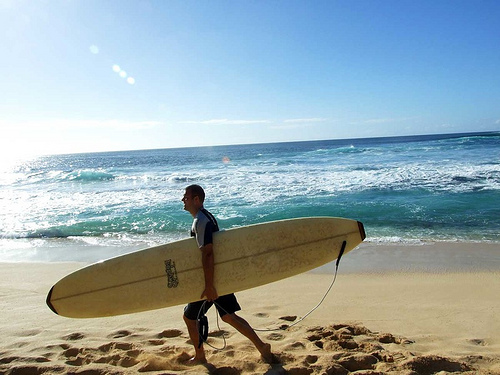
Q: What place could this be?
A: It is a beach.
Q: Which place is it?
A: It is a beach.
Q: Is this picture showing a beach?
A: Yes, it is showing a beach.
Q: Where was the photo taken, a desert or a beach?
A: It was taken at a beach.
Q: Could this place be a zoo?
A: No, it is a beach.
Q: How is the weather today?
A: It is sunny.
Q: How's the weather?
A: It is sunny.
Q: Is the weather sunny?
A: Yes, it is sunny.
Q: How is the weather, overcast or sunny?
A: It is sunny.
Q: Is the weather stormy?
A: No, it is sunny.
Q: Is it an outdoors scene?
A: Yes, it is outdoors.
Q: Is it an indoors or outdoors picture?
A: It is outdoors.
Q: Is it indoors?
A: No, it is outdoors.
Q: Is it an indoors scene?
A: No, it is outdoors.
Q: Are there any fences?
A: No, there are no fences.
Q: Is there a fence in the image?
A: No, there are no fences.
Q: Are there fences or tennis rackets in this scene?
A: No, there are no fences or tennis rackets.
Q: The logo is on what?
A: The logo is on the surf board.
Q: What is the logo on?
A: The logo is on the surf board.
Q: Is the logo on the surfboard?
A: Yes, the logo is on the surfboard.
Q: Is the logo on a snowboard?
A: No, the logo is on the surfboard.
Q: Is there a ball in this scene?
A: No, there are no balls.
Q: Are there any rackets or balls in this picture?
A: No, there are no balls or rackets.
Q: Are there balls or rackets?
A: No, there are no balls or rackets.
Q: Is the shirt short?
A: Yes, the shirt is short.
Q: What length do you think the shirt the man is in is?
A: The shirt is short.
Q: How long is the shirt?
A: The shirt is short.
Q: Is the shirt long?
A: No, the shirt is short.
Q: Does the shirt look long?
A: No, the shirt is short.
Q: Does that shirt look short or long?
A: The shirt is short.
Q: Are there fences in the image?
A: No, there are no fences.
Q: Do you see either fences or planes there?
A: No, there are no fences or planes.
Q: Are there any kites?
A: No, there are no kites.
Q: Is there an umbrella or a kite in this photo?
A: No, there are no kites or umbrellas.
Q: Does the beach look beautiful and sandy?
A: Yes, the beach is beautiful and sandy.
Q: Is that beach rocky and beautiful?
A: No, the beach is beautiful but sandy.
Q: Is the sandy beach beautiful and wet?
A: Yes, the beach is beautiful and wet.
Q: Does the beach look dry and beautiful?
A: No, the beach is beautiful but wet.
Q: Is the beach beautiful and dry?
A: No, the beach is beautiful but wet.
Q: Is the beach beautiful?
A: Yes, the beach is beautiful.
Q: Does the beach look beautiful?
A: Yes, the beach is beautiful.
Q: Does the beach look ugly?
A: No, the beach is beautiful.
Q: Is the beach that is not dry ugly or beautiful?
A: The beach is beautiful.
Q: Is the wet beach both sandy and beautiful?
A: Yes, the beach is sandy and beautiful.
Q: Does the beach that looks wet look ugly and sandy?
A: No, the beach is sandy but beautiful.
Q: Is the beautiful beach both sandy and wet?
A: Yes, the beach is sandy and wet.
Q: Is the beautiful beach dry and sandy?
A: No, the beach is sandy but wet.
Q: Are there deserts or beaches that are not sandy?
A: No, there is a beach but it is sandy.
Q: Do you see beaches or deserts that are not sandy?
A: No, there is a beach but it is sandy.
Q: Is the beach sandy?
A: Yes, the beach is sandy.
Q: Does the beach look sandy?
A: Yes, the beach is sandy.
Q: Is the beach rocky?
A: No, the beach is sandy.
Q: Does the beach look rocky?
A: No, the beach is sandy.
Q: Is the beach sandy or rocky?
A: The beach is sandy.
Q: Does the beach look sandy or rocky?
A: The beach is sandy.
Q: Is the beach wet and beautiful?
A: Yes, the beach is wet and beautiful.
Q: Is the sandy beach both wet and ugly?
A: No, the beach is wet but beautiful.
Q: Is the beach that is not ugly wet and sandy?
A: Yes, the beach is wet and sandy.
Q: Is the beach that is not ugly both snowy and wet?
A: No, the beach is wet but sandy.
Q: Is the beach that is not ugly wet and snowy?
A: No, the beach is wet but sandy.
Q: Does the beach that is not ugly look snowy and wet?
A: No, the beach is wet but sandy.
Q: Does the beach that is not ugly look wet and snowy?
A: No, the beach is wet but sandy.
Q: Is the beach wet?
A: Yes, the beach is wet.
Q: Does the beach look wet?
A: Yes, the beach is wet.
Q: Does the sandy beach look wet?
A: Yes, the beach is wet.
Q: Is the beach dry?
A: No, the beach is wet.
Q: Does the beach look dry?
A: No, the beach is wet.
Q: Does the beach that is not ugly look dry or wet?
A: The beach is wet.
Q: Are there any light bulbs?
A: No, there are no light bulbs.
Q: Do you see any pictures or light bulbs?
A: No, there are no light bulbs or pictures.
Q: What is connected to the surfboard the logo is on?
A: The rope is connected to the surfboard.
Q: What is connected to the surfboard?
A: The rope is connected to the surfboard.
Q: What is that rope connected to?
A: The rope is connected to the surfboard.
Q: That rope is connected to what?
A: The rope is connected to the surfboard.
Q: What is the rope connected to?
A: The rope is connected to the surfboard.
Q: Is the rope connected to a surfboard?
A: Yes, the rope is connected to a surfboard.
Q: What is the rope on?
A: The rope is on the surfboard.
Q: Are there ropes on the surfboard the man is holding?
A: Yes, there is a rope on the surfboard.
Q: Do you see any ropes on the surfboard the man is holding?
A: Yes, there is a rope on the surfboard.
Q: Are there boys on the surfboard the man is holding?
A: No, there is a rope on the surfboard.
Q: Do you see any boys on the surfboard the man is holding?
A: No, there is a rope on the surfboard.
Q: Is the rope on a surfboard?
A: Yes, the rope is on a surfboard.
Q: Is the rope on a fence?
A: No, the rope is on a surfboard.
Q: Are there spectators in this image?
A: No, there are no spectators.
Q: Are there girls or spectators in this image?
A: No, there are no spectators or girls.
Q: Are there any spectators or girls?
A: No, there are no spectators or girls.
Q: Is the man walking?
A: Yes, the man is walking.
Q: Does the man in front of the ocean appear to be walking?
A: Yes, the man is walking.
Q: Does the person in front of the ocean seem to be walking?
A: Yes, the man is walking.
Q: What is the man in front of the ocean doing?
A: The man is walking.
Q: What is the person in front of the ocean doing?
A: The man is walking.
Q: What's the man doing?
A: The man is walking.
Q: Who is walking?
A: The man is walking.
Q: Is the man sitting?
A: No, the man is walking.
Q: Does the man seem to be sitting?
A: No, the man is walking.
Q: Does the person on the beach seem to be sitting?
A: No, the man is walking.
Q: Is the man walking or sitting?
A: The man is walking.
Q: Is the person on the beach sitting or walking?
A: The man is walking.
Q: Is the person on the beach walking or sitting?
A: The man is walking.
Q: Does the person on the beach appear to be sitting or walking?
A: The man is walking.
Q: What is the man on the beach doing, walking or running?
A: The man is walking.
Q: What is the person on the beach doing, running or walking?
A: The man is walking.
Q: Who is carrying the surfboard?
A: The man is carrying the surfboard.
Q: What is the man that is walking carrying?
A: The man is carrying a surfboard.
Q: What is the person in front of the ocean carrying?
A: The man is carrying a surfboard.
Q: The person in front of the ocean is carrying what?
A: The man is carrying a surfboard.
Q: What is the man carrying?
A: The man is carrying a surfboard.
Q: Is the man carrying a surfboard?
A: Yes, the man is carrying a surfboard.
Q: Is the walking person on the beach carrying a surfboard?
A: Yes, the man is carrying a surfboard.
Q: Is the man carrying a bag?
A: No, the man is carrying a surfboard.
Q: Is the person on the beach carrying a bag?
A: No, the man is carrying a surfboard.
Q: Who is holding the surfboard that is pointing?
A: The man is holding the surfboard.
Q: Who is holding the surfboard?
A: The man is holding the surfboard.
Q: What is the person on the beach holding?
A: The man is holding the surfboard.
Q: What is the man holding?
A: The man is holding the surfboard.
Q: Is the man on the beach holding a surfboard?
A: Yes, the man is holding a surfboard.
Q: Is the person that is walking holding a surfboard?
A: Yes, the man is holding a surfboard.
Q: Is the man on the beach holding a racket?
A: No, the man is holding a surfboard.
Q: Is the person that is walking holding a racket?
A: No, the man is holding a surfboard.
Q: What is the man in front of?
A: The man is in front of the ocean.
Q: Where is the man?
A: The man is on the beach.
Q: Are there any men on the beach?
A: Yes, there is a man on the beach.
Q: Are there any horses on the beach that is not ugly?
A: No, there is a man on the beach.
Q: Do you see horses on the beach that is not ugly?
A: No, there is a man on the beach.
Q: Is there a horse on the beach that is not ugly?
A: No, there is a man on the beach.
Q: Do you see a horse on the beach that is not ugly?
A: No, there is a man on the beach.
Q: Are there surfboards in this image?
A: Yes, there is a surfboard.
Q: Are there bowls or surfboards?
A: Yes, there is a surfboard.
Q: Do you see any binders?
A: No, there are no binders.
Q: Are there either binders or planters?
A: No, there are no binders or planters.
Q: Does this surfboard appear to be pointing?
A: Yes, the surfboard is pointing.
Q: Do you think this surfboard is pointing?
A: Yes, the surfboard is pointing.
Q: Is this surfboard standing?
A: No, the surfboard is pointing.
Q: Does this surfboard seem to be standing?
A: No, the surfboard is pointing.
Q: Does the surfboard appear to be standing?
A: No, the surfboard is pointing.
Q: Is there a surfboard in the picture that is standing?
A: No, there is a surfboard but it is pointing.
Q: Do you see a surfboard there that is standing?
A: No, there is a surfboard but it is pointing.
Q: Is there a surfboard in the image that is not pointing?
A: No, there is a surfboard but it is pointing.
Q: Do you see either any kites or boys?
A: No, there are no kites or boys.